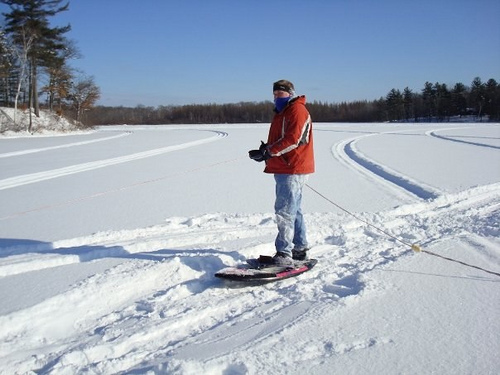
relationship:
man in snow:
[244, 75, 316, 270] [0, 109, 500, 372]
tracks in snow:
[331, 129, 442, 200] [0, 109, 500, 372]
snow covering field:
[0, 109, 500, 372] [10, 126, 500, 370]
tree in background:
[383, 89, 408, 126] [5, 3, 500, 136]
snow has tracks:
[0, 109, 500, 372] [331, 129, 442, 200]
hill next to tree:
[4, 103, 84, 133] [8, 5, 73, 115]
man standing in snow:
[244, 75, 316, 270] [0, 109, 500, 372]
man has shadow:
[244, 75, 316, 270] [7, 229, 258, 272]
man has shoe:
[244, 75, 316, 270] [271, 249, 297, 267]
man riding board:
[244, 75, 316, 270] [213, 253, 320, 284]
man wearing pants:
[244, 75, 316, 270] [268, 171, 309, 252]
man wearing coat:
[244, 75, 316, 270] [262, 92, 320, 173]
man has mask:
[244, 75, 316, 270] [272, 95, 291, 116]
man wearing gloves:
[244, 75, 316, 270] [249, 143, 271, 161]